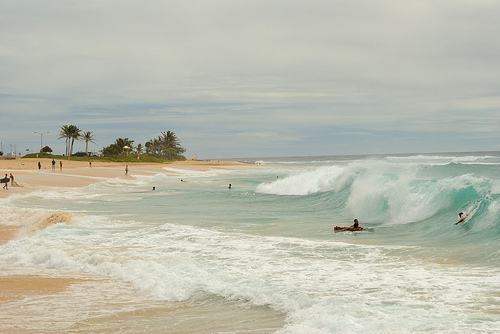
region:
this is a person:
[326, 180, 381, 237]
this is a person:
[453, 171, 488, 242]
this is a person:
[225, 165, 247, 205]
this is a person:
[149, 180, 164, 205]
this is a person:
[171, 167, 193, 196]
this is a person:
[32, 157, 52, 174]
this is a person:
[43, 147, 57, 177]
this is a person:
[74, 147, 108, 175]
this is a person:
[3, 171, 16, 200]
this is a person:
[51, 152, 73, 176]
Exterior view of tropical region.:
[6, 10, 496, 330]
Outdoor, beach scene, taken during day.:
[0, 12, 496, 330]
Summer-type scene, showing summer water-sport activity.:
[5, 15, 490, 330]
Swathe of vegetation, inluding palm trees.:
[12, 115, 188, 165]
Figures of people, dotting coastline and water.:
[0, 155, 338, 206]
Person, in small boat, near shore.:
[326, 218, 383, 239]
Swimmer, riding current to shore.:
[452, 196, 477, 226]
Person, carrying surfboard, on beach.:
[0, 166, 15, 192]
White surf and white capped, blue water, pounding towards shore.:
[25, 157, 477, 322]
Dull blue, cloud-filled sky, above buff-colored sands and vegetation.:
[7, 15, 288, 179]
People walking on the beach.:
[34, 156, 65, 173]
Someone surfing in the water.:
[332, 216, 373, 233]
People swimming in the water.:
[143, 175, 240, 192]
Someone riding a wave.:
[451, 200, 484, 225]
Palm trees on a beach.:
[54, 123, 99, 159]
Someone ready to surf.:
[1, 171, 11, 189]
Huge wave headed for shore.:
[261, 150, 446, 220]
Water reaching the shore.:
[0, 208, 119, 275]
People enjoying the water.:
[138, 175, 238, 197]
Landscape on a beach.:
[100, 130, 190, 164]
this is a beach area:
[12, 103, 495, 310]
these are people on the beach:
[4, 128, 196, 202]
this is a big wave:
[236, 153, 498, 243]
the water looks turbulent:
[124, 154, 492, 311]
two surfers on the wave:
[318, 196, 489, 246]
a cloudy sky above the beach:
[10, 39, 482, 159]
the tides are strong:
[18, 201, 275, 319]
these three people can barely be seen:
[146, 171, 249, 206]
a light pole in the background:
[26, 123, 59, 154]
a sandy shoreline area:
[10, 171, 241, 308]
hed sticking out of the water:
[221, 180, 243, 195]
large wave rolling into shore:
[257, 154, 496, 251]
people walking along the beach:
[29, 154, 66, 173]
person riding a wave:
[450, 206, 475, 229]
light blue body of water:
[115, 148, 497, 315]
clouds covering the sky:
[2, 1, 499, 156]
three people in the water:
[136, 171, 239, 204]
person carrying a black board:
[1, 170, 13, 192]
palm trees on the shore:
[54, 119, 96, 153]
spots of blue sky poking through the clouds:
[104, 93, 499, 160]